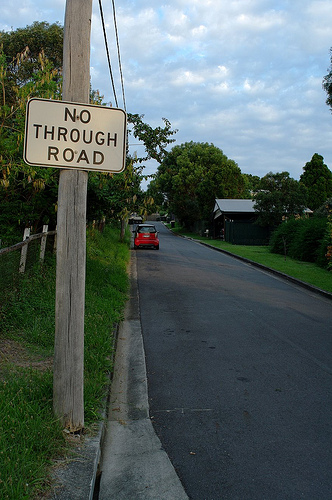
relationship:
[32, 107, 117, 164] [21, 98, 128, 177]
wording on sign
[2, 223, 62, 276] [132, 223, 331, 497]
fence by street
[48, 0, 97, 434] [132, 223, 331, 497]
pole by street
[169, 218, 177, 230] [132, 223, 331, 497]
trash on street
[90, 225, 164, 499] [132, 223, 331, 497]
curb by street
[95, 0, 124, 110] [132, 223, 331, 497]
wire above street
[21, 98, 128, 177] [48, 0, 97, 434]
sign on pole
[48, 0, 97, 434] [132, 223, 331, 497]
pole near street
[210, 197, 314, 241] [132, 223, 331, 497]
building by street